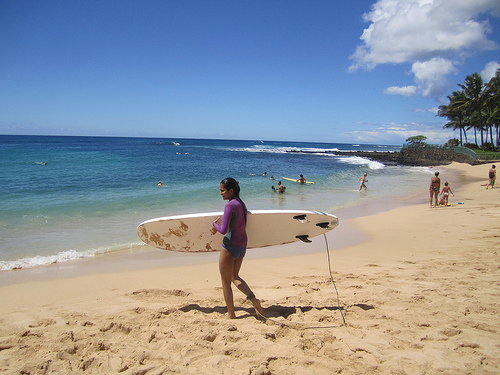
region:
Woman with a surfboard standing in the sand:
[134, 178, 347, 323]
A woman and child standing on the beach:
[421, 168, 466, 214]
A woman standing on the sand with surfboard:
[133, 178, 345, 330]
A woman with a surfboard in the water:
[282, 171, 321, 189]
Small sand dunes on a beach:
[28, 313, 365, 374]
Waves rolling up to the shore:
[6, 223, 131, 340]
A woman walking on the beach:
[481, 163, 499, 195]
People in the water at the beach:
[256, 164, 383, 200]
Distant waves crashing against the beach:
[243, 142, 465, 169]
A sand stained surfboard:
[132, 208, 346, 254]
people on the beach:
[120, 153, 475, 343]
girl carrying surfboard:
[116, 168, 358, 335]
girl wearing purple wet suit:
[203, 170, 272, 330]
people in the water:
[253, 166, 320, 201]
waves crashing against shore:
[243, 137, 387, 177]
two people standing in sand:
[424, 165, 455, 211]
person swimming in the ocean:
[150, 175, 174, 192]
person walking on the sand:
[484, 158, 495, 195]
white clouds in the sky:
[337, 45, 448, 112]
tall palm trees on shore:
[440, 73, 499, 152]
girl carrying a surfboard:
[126, 171, 353, 339]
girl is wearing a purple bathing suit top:
[201, 192, 253, 259]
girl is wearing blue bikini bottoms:
[220, 235, 261, 278]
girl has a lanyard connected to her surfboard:
[235, 192, 366, 344]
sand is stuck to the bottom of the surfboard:
[126, 185, 229, 252]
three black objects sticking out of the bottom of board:
[281, 198, 341, 264]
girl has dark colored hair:
[216, 181, 252, 226]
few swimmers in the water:
[250, 165, 346, 210]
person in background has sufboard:
[275, 165, 326, 208]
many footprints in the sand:
[76, 288, 336, 374]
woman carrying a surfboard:
[134, 161, 373, 331]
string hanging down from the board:
[319, 223, 353, 335]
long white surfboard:
[129, 186, 356, 273]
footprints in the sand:
[32, 286, 461, 374]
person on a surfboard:
[279, 169, 326, 189]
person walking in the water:
[354, 165, 379, 195]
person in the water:
[150, 177, 171, 189]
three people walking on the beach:
[407, 154, 497, 212]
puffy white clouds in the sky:
[347, 2, 499, 110]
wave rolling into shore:
[0, 240, 103, 275]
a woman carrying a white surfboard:
[127, 172, 350, 325]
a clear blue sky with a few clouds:
[1, 0, 498, 140]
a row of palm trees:
[432, 70, 499, 152]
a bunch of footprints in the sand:
[3, 299, 474, 374]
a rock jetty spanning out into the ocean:
[288, 144, 460, 167]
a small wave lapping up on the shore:
[2, 248, 114, 271]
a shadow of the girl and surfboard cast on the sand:
[176, 291, 377, 321]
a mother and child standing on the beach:
[427, 168, 456, 210]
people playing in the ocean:
[249, 164, 317, 196]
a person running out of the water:
[355, 170, 374, 193]